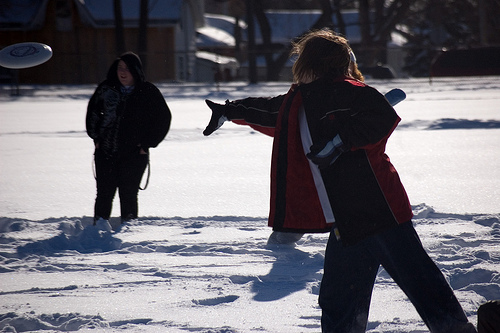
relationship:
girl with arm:
[203, 26, 475, 333] [201, 91, 296, 141]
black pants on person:
[90, 154, 147, 218] [90, 39, 155, 218]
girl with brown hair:
[203, 26, 475, 333] [289, 31, 364, 88]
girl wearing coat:
[203, 26, 475, 333] [225, 79, 412, 232]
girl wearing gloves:
[203, 26, 475, 333] [305, 123, 349, 170]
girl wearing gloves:
[203, 26, 475, 333] [202, 92, 226, 132]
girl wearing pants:
[203, 26, 475, 333] [314, 212, 476, 332]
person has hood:
[80, 52, 170, 224] [111, 46, 147, 67]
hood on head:
[111, 46, 147, 67] [110, 50, 144, 86]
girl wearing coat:
[203, 26, 475, 333] [79, 79, 172, 151]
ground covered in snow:
[0, 73, 498, 331] [1, 79, 498, 326]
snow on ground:
[170, 240, 232, 296] [173, 138, 239, 215]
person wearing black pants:
[84, 52, 171, 225] [92, 145, 151, 226]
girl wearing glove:
[203, 26, 475, 333] [186, 88, 227, 148]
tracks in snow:
[0, 204, 494, 331] [1, 79, 498, 326]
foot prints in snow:
[40, 238, 185, 320] [185, 296, 234, 327]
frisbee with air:
[4, 34, 61, 81] [3, 20, 93, 96]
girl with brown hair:
[203, 26, 475, 333] [288, 27, 365, 86]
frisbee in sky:
[0, 42, 53, 68] [4, 4, 474, 55]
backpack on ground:
[465, 296, 498, 330] [6, 86, 483, 309]